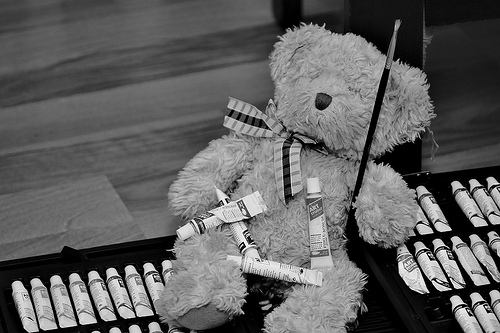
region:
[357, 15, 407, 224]
the teddy bear has a paint brush resting between its hand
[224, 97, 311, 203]
the teddy bear has a ribbon tied around its neck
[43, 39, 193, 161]
the floor is wooden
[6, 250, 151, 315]
their are many tubes of differen't colors of paint in a tray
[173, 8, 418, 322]
the teddybear is sitting on a tray with tubes of all different colors of paint in them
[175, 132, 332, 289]
the teddybear has four tubes of paint strewn on its body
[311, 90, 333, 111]
the teddybear has a brown or black nose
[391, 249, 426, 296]
the tube of paint has been used a lot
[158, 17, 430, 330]
the teddybear is probably a light brown color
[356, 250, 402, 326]
the color of the tray the tubes of paint are in is black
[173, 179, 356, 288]
Tubes of paint laying on teddy bear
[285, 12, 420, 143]
Teddy bears fuzzy head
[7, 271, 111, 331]
Tray of paint lined up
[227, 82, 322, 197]
Bow around teddy bears neck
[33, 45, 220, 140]
Wood grained table top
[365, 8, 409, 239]
Bear holding a paintbrush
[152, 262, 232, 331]
Teddy bear fuzzy foot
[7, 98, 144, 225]
Wooden floor boards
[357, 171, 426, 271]
Fluffy paw of teddy bear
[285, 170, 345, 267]
Tube of paint sitting upright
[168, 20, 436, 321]
a teddy bear without eyes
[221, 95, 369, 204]
a bow is around the bear's neck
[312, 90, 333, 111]
the bear has a black nose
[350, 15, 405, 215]
a paint brush is on the bear's arm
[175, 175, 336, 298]
tubes of paint are scattered on the bear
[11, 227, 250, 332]
tubes are lined up in a black box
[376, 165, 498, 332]
tubes are in line in the box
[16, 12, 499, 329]
the black boxes are on the floor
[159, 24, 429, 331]
the bear is sitting in the boxes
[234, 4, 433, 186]
the bear is leaning against a chair leg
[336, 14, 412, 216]
a kids size paintbrush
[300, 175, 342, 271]
paint in a tube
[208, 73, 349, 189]
teddy bear ribbon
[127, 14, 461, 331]
a teddy bear with art supplies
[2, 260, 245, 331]
a paint set in tubes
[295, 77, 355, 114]
teddy bears nose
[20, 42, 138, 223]
hardwood floor of different shades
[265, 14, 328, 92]
teddy bear ear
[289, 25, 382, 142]
the face of the teddy bear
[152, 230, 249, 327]
the foot of the teddy bear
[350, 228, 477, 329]
colored tubes of paint.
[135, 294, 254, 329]
brown teddy bear's foot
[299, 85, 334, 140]
brown teddy bears nose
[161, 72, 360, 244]
ribbon on teddy bears neck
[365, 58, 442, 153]
teddy bears brown ear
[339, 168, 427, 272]
teddy bears brown paw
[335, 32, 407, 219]
black handled paint brush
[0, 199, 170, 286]
black paint holder tray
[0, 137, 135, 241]
wooden floor tray and teddy bear are sitting on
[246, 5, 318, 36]
chair leg in back of teddy bear